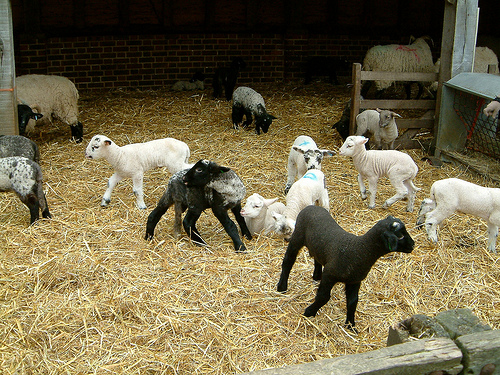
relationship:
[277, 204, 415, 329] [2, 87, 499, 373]
lamb in hay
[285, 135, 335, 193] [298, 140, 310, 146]
lamb has marking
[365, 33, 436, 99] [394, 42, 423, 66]
sheep with marking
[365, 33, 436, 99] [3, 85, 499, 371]
sheep in pen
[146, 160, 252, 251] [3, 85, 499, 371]
sheep in pen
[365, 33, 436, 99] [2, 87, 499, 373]
sheep on hay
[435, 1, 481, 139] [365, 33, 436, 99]
wood near sheep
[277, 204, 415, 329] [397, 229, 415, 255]
lamb has a face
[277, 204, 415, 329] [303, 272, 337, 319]
lamb has a leg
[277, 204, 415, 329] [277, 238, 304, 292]
lamb has a leg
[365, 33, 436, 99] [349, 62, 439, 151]
sheep near fence